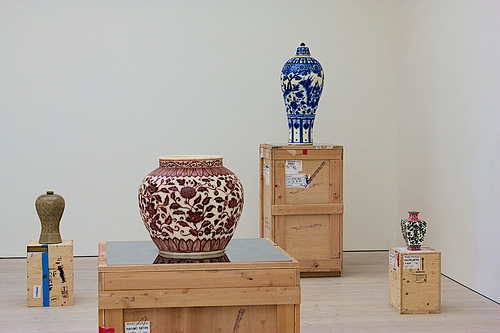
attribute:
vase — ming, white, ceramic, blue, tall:
[281, 41, 324, 145]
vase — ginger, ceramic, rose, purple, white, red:
[137, 153, 246, 264]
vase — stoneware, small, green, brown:
[37, 191, 67, 246]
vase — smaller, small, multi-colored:
[400, 210, 427, 251]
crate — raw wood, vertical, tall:
[259, 143, 345, 279]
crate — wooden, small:
[28, 237, 76, 304]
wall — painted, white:
[1, 2, 399, 257]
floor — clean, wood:
[3, 251, 500, 332]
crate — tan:
[98, 238, 298, 332]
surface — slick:
[103, 237, 293, 266]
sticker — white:
[286, 174, 311, 190]